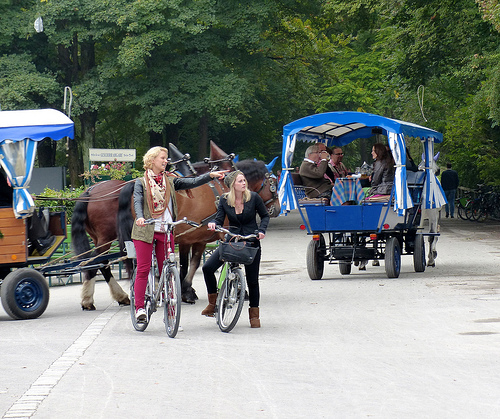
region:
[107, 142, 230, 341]
blonde woman pointing to her left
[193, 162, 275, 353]
woman dressed in black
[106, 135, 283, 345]
two attractive woman on bikes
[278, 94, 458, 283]
group of people on a blue carriage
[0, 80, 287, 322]
brown horse pulling a carriage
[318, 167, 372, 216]
pink and blue table cloth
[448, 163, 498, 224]
bikes parked at a bike stand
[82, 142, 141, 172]
white and blue rectangular sign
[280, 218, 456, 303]
the carriage has four wheels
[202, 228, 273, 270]
black basket on from of the bike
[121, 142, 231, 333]
Blond woman wearing pink jeans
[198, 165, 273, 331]
Blond woman wearing black jeans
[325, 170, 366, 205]
Blue and pink plaid table cloth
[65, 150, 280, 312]
Brown horse pulling a carriage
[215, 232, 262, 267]
Black metal mesh bicycle basket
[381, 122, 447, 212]
Blue and white curtains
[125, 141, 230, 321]
Young woman pointing at something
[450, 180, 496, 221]
Bicycles attached to a railing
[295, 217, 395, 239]
Red and orange reflectors on the back of a carriage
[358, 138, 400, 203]
Woman wearing a gray jacket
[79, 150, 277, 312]
a dark brown horse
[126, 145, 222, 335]
a woman on a bicycle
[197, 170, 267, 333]
a woman on a bicycle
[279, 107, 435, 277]
a blue covered wagon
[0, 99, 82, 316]
a blue covered wagon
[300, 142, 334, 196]
a man riding in a wagon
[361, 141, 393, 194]
a woman riding in a wagon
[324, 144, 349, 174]
a man riding in a wagon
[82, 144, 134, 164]
a white street sign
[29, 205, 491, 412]
a white paved road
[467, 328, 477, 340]
black mark is spotted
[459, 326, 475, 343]
black mark is spotted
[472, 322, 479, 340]
black mark is spotted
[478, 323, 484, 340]
black mark is spotted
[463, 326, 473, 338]
black mark is spotted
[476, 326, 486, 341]
black mark is spotted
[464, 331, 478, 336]
black mark is spotted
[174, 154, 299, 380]
a woman on a bicycle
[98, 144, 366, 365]
two women on bicycles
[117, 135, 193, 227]
a woman wearing a scarf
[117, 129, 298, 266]
a brown horse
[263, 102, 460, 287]
people sitting in a blue carriage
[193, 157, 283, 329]
a bicycle with a basket on the front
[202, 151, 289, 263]
a woman wearing a hat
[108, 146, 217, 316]
a woman wearing pink pants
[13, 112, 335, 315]
horses towing a carriage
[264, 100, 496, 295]
a blue and white carriage